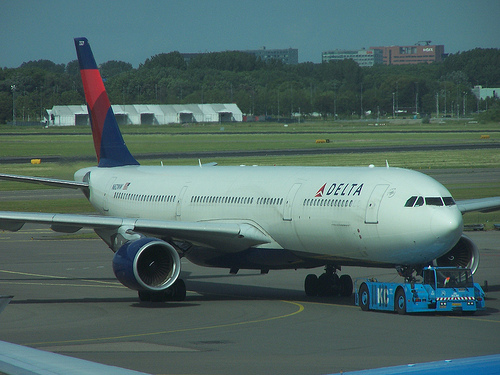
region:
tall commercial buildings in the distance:
[145, 35, 480, 86]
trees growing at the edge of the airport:
[135, 40, 495, 146]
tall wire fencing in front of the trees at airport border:
[245, 75, 490, 135]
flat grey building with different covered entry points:
[36, 95, 262, 135]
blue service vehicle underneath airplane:
[256, 116, 486, 323]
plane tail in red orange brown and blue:
[61, 30, 141, 170]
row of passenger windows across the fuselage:
[97, 185, 362, 210]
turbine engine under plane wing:
[21, 147, 286, 302]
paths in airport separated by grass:
[127, 115, 485, 177]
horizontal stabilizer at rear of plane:
[8, 156, 98, 203]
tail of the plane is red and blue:
[66, 27, 153, 174]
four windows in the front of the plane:
[393, 187, 468, 219]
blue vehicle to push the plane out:
[356, 244, 491, 346]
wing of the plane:
[0, 192, 282, 299]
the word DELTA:
[308, 170, 378, 205]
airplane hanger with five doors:
[44, 87, 246, 134]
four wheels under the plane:
[292, 261, 357, 309]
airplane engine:
[108, 232, 209, 300]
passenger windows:
[104, 185, 358, 215]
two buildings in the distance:
[311, 29, 450, 81]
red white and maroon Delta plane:
[3, 38, 495, 302]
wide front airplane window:
[405, 193, 415, 210]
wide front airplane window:
[414, 196, 426, 208]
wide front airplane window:
[424, 194, 444, 206]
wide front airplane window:
[444, 195, 455, 207]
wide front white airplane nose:
[403, 176, 467, 258]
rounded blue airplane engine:
[113, 235, 182, 288]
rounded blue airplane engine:
[436, 234, 480, 280]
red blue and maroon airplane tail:
[75, 34, 149, 173]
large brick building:
[376, 42, 444, 67]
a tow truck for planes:
[328, 235, 484, 333]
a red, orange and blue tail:
[69, 26, 136, 188]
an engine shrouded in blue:
[110, 234, 181, 296]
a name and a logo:
[310, 179, 368, 199]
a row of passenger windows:
[109, 187, 359, 208]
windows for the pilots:
[399, 189, 461, 211]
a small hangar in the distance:
[34, 91, 259, 151]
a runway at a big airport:
[0, 118, 493, 170]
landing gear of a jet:
[296, 248, 365, 313]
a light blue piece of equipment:
[344, 263, 489, 340]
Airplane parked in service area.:
[12, 11, 487, 312]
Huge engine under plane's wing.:
[109, 229, 189, 304]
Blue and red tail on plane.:
[81, 101, 143, 169]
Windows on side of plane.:
[183, 188, 295, 218]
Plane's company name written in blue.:
[310, 175, 371, 204]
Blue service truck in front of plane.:
[343, 266, 490, 321]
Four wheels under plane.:
[302, 269, 357, 306]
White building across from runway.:
[50, 92, 251, 131]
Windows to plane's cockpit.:
[398, 186, 458, 210]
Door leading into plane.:
[278, 183, 305, 225]